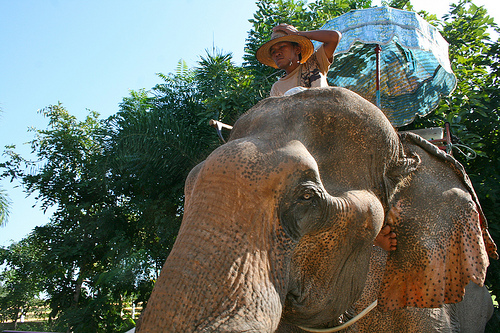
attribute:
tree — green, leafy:
[0, 2, 495, 332]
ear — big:
[387, 130, 498, 310]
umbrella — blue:
[307, 9, 468, 123]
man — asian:
[238, 24, 341, 89]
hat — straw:
[255, 24, 318, 61]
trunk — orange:
[156, 211, 292, 331]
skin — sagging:
[293, 255, 368, 329]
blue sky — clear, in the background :
[10, 0, 197, 95]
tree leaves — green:
[13, 68, 239, 319]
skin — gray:
[316, 136, 365, 186]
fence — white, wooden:
[3, 295, 149, 325]